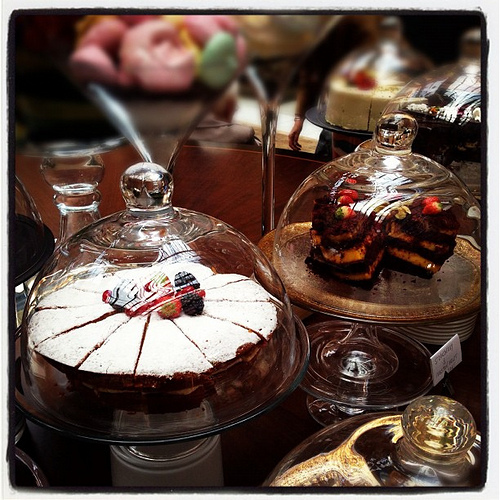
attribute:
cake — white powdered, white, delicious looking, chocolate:
[28, 266, 279, 414]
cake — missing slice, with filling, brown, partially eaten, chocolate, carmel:
[305, 175, 457, 291]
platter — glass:
[11, 298, 309, 447]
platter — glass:
[256, 220, 485, 323]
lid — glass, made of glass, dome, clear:
[21, 162, 298, 435]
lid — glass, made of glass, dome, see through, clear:
[275, 113, 483, 318]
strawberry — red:
[424, 202, 443, 213]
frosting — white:
[29, 263, 277, 376]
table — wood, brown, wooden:
[14, 137, 481, 487]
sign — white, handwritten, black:
[429, 333, 463, 387]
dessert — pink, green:
[65, 16, 248, 92]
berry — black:
[181, 292, 202, 316]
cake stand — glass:
[253, 271, 484, 410]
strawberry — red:
[336, 205, 355, 220]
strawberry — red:
[339, 193, 355, 205]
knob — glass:
[373, 115, 418, 157]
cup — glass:
[75, 83, 235, 172]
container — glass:
[317, 17, 436, 132]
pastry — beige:
[327, 75, 411, 131]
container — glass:
[384, 30, 484, 196]